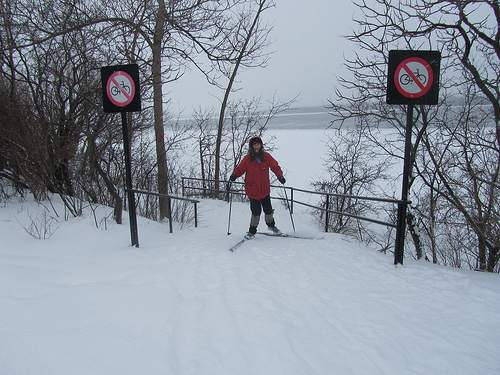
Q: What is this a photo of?
A: A man skiing.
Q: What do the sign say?
A: No bikes.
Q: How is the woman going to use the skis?
A: Skiing on the snow.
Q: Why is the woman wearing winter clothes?
A: To keep warm.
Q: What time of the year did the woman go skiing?
A: Winter.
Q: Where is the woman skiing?
A: Resort.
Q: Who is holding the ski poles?
A: A woman in a red coat.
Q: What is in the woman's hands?
A: Ski poles.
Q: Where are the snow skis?
A: On the woman's feet.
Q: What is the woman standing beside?
A: A metal handrail.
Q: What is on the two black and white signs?
A: "No Bikes Allowed" symbol.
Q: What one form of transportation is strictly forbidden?
A: Bicycle.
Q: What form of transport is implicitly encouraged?
A: Skiing.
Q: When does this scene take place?
A: Winter.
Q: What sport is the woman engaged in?
A: Skiing.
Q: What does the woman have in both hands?
A: Ski poles.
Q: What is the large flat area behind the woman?
A: River.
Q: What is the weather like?
A: Cloudy and cold.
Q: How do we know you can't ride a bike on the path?
A: Signs.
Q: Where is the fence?
A: Behind the skier.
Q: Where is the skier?
A: Between the two signs.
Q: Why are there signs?
A: Warning against bikes.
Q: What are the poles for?
A: Signs.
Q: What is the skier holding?
A: Ski poles.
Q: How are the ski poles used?
A: Guidance.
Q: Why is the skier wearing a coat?
A: Protection from cold.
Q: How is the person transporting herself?
A: Skis.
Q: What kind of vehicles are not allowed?
A: Bicycles.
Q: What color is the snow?
A: White.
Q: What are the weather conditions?
A: Cloudy.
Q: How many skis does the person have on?
A: Two.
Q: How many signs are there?
A: Two.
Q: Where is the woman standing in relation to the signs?
A: Between.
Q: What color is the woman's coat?
A: Red.